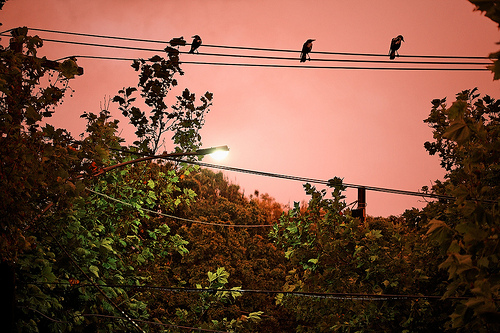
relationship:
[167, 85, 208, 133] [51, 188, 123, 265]
leaves on a branch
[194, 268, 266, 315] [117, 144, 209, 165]
leaves on a branch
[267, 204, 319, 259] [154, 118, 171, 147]
leaves on a branch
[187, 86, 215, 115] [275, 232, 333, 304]
leaves on a branch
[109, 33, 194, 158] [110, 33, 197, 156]
leaves on a branch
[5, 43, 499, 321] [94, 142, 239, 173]
leaves on a branch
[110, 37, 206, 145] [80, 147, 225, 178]
leaves on a branch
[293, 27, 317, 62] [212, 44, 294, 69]
bird sitting on wire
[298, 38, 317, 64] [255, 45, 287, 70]
bird sitting on wire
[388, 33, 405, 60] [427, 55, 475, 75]
bird sitting on wire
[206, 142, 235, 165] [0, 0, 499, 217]
sun sitting in sky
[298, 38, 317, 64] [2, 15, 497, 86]
bird sitting on telephone wire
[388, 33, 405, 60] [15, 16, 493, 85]
bird sitting on wire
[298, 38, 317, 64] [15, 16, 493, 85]
bird sitting on wire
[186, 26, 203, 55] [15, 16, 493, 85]
bird sitting on wire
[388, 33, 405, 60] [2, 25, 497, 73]
bird sitting on telephone wire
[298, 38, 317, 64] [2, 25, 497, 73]
bird sitting on telephone wire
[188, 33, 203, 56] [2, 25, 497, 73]
bird sitting on telephone wire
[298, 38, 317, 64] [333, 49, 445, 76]
bird sitting on telephone wire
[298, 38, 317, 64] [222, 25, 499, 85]
bird sitting on wire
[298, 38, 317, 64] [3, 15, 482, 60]
bird sitting on telephone wire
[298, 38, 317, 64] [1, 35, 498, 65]
bird sitting on telephone wire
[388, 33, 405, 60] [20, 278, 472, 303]
bird sitting on telephone wire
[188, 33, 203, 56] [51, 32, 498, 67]
bird sitting on telephone wire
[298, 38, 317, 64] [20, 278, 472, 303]
bird sitting on telephone wire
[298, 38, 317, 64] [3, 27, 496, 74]
bird on telephone wire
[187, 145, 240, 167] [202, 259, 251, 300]
light shines through leaves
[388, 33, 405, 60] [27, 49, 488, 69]
bird in middle of wire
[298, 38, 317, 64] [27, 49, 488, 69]
bird in middle of wire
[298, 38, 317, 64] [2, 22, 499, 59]
bird on top of wire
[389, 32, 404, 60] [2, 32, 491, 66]
bird on top of wire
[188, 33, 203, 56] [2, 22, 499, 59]
bird on top of wire